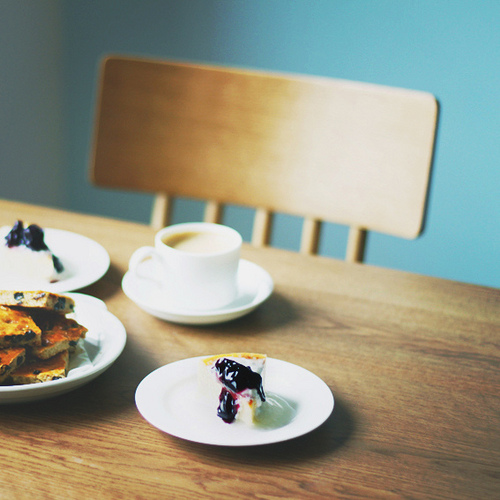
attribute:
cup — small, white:
[156, 235, 245, 290]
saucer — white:
[133, 282, 285, 320]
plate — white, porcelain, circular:
[140, 367, 362, 453]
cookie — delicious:
[19, 301, 72, 337]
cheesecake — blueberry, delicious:
[205, 355, 270, 413]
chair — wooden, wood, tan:
[109, 57, 452, 224]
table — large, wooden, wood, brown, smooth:
[310, 261, 493, 354]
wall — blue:
[265, 28, 479, 86]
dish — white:
[126, 363, 369, 443]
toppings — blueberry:
[209, 362, 258, 388]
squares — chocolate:
[9, 294, 82, 382]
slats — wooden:
[190, 203, 319, 249]